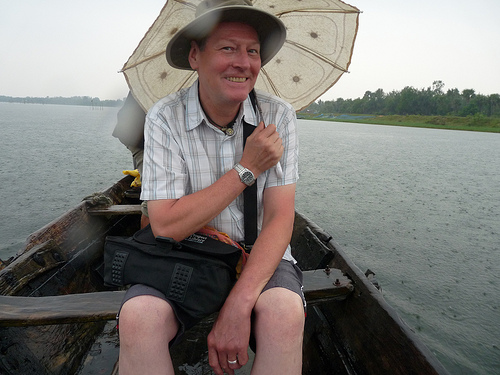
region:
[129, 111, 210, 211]
Zebra drinking water next to dirt.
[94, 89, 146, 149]
water droplet on camera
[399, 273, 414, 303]
rain drops making contact with water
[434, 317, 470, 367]
small waves form boat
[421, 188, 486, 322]
small ripples on water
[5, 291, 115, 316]
plank of wood for sitting on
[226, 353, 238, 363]
wedding band on wedding finger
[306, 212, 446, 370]
boat that man is sitting in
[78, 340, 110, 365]
water on floor of boat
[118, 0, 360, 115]
umbrella for shielding body form rain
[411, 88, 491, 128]
field of grass and line of trees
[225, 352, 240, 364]
Man wearing a ring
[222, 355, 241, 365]
Man is wearing a ring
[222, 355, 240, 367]
Man wearing a wedding ring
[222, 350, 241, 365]
Man is wearing a wedding ring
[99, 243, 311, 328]
Man wearing shorts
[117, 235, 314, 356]
Man is wearing shorts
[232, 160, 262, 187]
Man wearing a watch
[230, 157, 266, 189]
Man is wearing a watch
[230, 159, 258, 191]
Man wearing a wrist watch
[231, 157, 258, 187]
Man is wearing a wrist watch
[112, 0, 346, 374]
This is a person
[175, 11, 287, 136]
head of a person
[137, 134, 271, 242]
arm of a person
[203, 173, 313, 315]
arm of a person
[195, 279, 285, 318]
wrist of a person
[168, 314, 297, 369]
hand of a person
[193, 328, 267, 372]
finger of a person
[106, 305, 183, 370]
leg of a person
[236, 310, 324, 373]
leg of a person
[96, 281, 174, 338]
knee of a person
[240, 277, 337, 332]
knee of a person